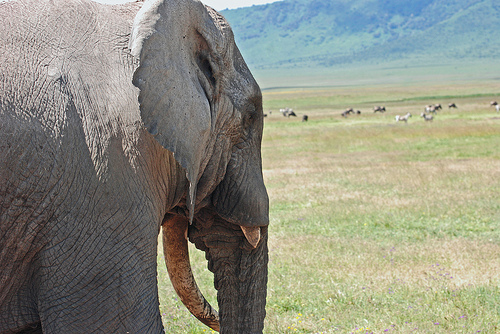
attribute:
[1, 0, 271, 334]
elephant — looking, gray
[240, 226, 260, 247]
tusk — small, missing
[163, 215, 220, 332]
tusk — large, dirty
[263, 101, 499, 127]
animals — grazing, distant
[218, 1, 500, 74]
hill — green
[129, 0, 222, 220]
ear — gray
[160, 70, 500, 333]
grass — green, brown, short, dry